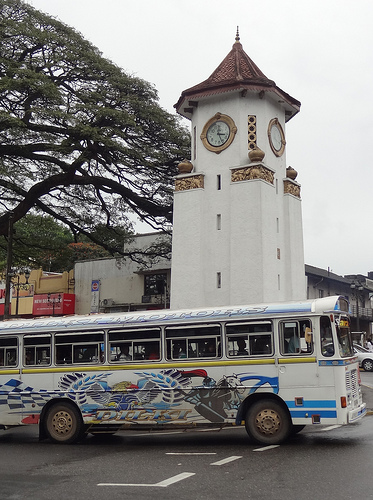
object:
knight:
[178, 369, 216, 407]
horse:
[189, 372, 245, 422]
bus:
[0, 295, 367, 445]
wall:
[183, 222, 213, 291]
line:
[253, 445, 280, 452]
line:
[210, 455, 244, 465]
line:
[165, 452, 217, 454]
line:
[97, 483, 167, 488]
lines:
[155, 472, 196, 486]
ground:
[0, 374, 372, 500]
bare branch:
[75, 174, 174, 223]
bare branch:
[59, 216, 117, 252]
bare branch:
[32, 152, 68, 173]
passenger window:
[164, 322, 222, 362]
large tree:
[0, 0, 190, 320]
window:
[23, 333, 52, 368]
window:
[54, 329, 106, 365]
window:
[107, 326, 162, 365]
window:
[278, 318, 315, 356]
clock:
[267, 116, 286, 157]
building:
[0, 25, 373, 334]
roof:
[172, 25, 300, 124]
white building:
[74, 88, 308, 316]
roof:
[75, 254, 124, 263]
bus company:
[1, 306, 268, 329]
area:
[0, 0, 372, 498]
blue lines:
[285, 399, 337, 417]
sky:
[9, 0, 373, 277]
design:
[0, 368, 337, 425]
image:
[57, 367, 192, 421]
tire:
[41, 402, 82, 445]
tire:
[245, 399, 293, 446]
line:
[134, 262, 171, 272]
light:
[341, 395, 351, 408]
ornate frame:
[215, 112, 235, 128]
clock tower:
[169, 25, 306, 308]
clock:
[200, 112, 237, 154]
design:
[248, 115, 257, 151]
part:
[228, 49, 261, 80]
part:
[77, 78, 131, 139]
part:
[287, 216, 300, 257]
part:
[282, 391, 293, 396]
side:
[0, 314, 338, 426]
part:
[183, 228, 215, 254]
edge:
[147, 416, 177, 427]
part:
[342, 394, 348, 402]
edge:
[252, 413, 257, 433]